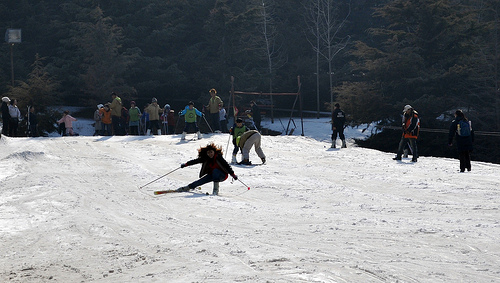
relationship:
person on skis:
[174, 140, 238, 195] [226, 169, 251, 198]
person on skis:
[174, 140, 238, 195] [136, 159, 191, 193]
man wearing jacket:
[390, 104, 419, 163] [399, 113, 416, 133]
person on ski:
[174, 140, 238, 195] [202, 189, 222, 196]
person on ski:
[174, 140, 238, 195] [153, 185, 182, 198]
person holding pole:
[182, 144, 236, 189] [233, 177, 250, 191]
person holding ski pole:
[182, 144, 236, 189] [140, 162, 181, 192]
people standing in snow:
[91, 86, 266, 137] [2, 104, 497, 281]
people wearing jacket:
[0, 87, 264, 140] [95, 100, 115, 125]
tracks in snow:
[347, 194, 496, 281] [2, 104, 497, 281]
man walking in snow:
[330, 104, 349, 149] [22, 135, 469, 279]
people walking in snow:
[0, 87, 264, 140] [203, 127, 229, 139]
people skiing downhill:
[0, 87, 264, 140] [0, 137, 497, 281]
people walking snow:
[0, 87, 264, 140] [11, 118, 482, 271]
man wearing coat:
[388, 102, 432, 194] [399, 101, 421, 148]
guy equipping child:
[241, 128, 268, 158] [227, 116, 251, 149]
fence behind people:
[252, 99, 330, 139] [105, 94, 236, 128]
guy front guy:
[232, 129, 266, 165] [232, 129, 266, 165]